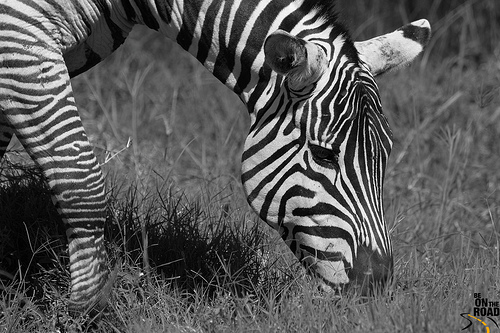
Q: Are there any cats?
A: No, there are no cats.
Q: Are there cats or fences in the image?
A: No, there are no cats or fences.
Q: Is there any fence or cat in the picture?
A: No, there are no cats or fences.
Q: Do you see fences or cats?
A: No, there are no cats or fences.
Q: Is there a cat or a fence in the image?
A: No, there are no cats or fences.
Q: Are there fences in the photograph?
A: No, there are no fences.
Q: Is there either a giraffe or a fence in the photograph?
A: No, there are no fences or giraffes.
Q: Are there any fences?
A: No, there are no fences.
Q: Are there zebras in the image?
A: Yes, there is a zebra.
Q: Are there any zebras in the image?
A: Yes, there is a zebra.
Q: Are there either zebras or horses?
A: Yes, there is a zebra.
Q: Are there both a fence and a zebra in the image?
A: No, there is a zebra but no fences.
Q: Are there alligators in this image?
A: No, there are no alligators.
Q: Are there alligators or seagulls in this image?
A: No, there are no alligators or seagulls.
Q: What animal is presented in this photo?
A: The animal is a zebra.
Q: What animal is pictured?
A: The animal is a zebra.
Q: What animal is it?
A: The animal is a zebra.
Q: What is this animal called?
A: This is a zebra.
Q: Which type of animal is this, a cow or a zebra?
A: This is a zebra.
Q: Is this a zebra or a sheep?
A: This is a zebra.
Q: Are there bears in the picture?
A: No, there are no bears.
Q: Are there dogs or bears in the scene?
A: No, there are no bears or dogs.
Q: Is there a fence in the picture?
A: No, there are no fences.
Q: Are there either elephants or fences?
A: No, there are no fences or elephants.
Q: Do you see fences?
A: No, there are no fences.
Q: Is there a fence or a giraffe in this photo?
A: No, there are no fences or giraffes.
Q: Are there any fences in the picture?
A: No, there are no fences.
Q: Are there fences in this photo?
A: No, there are no fences.